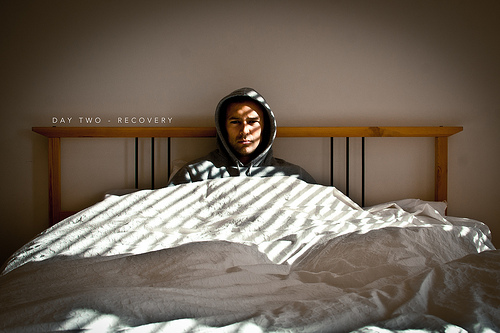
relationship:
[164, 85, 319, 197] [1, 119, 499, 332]
man in bed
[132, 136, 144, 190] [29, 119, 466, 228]
pole under headboard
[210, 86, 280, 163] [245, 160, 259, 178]
hood has string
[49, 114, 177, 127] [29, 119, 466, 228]
words above headboard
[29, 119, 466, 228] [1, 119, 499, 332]
headboard attached to bed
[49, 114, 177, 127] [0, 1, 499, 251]
words written on wall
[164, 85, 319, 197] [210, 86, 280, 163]
man wearing hood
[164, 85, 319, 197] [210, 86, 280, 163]
man has hood